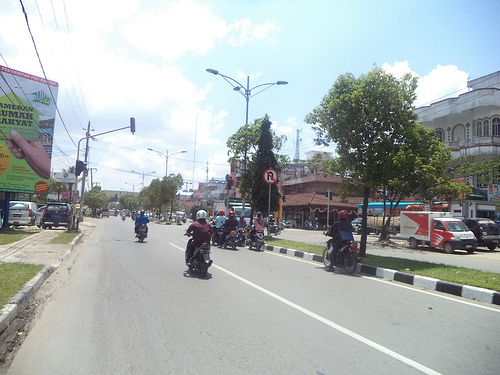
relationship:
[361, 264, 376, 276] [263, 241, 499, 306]
paint on curb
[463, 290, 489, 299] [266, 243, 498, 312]
white paint on curb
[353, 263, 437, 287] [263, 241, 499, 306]
paint on curb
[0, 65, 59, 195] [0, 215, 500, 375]
billboard on side of road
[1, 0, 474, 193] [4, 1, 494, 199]
clouds in sky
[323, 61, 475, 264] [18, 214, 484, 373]
tree on side of road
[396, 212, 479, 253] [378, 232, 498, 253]
red/white truck in parking lot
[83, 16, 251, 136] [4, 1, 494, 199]
clouds in sky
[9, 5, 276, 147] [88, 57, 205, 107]
clouds in sky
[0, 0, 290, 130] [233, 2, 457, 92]
clouds in sky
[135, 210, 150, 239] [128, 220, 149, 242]
motorcyclist riding motorcycle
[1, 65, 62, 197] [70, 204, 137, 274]
billboard side road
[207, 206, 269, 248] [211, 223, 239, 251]
people rides motorcycle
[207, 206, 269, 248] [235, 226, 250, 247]
people rides motorcycle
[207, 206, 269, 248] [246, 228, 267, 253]
people rides motorcycle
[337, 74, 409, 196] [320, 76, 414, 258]
leaves in tree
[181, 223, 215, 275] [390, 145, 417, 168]
motorcycle on ground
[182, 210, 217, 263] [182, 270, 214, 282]
cyclist has shadow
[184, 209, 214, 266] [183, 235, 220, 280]
cyclist rides motorcycle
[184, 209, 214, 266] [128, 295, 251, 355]
cyclist on road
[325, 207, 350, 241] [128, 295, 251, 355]
motorcyclist on road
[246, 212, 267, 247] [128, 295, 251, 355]
people on road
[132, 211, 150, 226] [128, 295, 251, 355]
motorcyclist on road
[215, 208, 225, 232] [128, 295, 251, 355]
motorcyclist on road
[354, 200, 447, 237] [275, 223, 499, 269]
bus on road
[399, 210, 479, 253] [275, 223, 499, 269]
red/white truck on road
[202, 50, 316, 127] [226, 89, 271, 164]
street lamps on poles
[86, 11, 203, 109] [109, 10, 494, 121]
clouds in sky